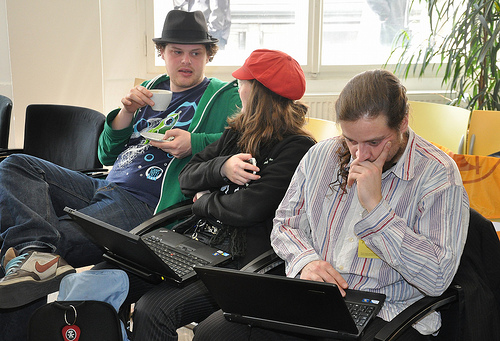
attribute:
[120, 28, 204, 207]
guy — sitting down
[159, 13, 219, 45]
hat — black, medium sized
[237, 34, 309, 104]
hat — red, orange-red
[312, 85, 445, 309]
guy — in white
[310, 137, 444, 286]
shirt — white, striped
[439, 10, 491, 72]
tree — green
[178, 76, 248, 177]
sweatshirt — green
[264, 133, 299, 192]
jacket — black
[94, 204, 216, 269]
laptop — black, plastic, computer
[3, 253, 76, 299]
sneakers — nike, green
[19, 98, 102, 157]
chair — empty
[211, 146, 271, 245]
shirt — black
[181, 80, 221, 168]
sweater — green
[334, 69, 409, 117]
hair — brown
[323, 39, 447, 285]
man — working, sitting down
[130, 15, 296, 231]
people — talking, three, beside each other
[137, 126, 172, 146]
saucer — white, small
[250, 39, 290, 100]
cap — red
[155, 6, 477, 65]
window — part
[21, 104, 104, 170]
seat — black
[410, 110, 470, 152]
seat — yellow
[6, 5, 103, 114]
wall — white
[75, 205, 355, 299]
laptops — black, computers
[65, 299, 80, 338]
keychain — red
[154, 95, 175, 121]
teacup — white, small